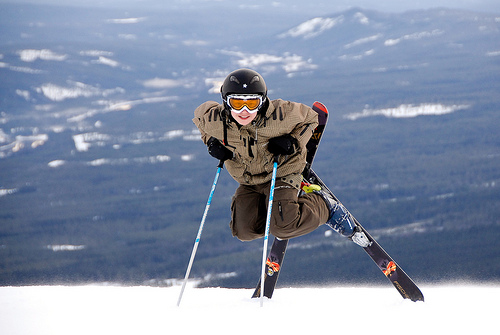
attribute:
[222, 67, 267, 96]
helmet — black 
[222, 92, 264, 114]
glasses — orange, silver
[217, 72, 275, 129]
helmet — black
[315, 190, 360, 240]
boot — blue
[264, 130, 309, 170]
glove — black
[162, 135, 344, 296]
poles — blue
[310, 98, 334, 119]
tip — red